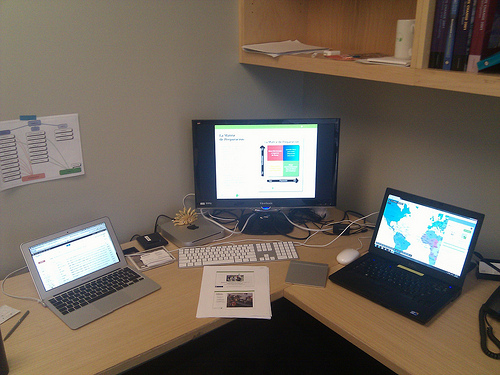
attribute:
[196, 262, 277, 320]
paper — white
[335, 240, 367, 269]
mouse — white 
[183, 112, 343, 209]
monitor — black, computer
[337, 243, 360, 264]
mouse — computer, white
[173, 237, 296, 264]
keyboard — white 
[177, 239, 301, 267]
keyboard — white computer , silver  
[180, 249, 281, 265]
keys — white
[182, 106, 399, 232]
monitor — black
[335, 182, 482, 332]
laptop — black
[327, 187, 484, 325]
laptop — black, on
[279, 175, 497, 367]
laptop — open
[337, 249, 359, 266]
mouse — white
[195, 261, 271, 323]
paper — piece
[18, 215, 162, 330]
laptop — silver, open, black, grey, on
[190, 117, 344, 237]
computer — working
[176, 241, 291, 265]
keys — white 